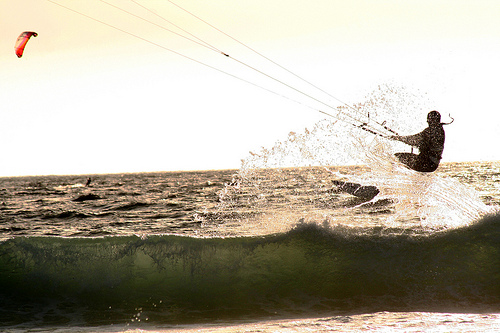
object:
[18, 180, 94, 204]
water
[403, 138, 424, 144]
elbow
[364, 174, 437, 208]
splash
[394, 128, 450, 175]
costume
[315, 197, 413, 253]
wave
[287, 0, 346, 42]
cloud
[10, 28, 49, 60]
kite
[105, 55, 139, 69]
sky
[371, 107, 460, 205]
man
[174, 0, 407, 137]
cord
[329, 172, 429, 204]
surfboard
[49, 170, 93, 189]
bird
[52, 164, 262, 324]
ocean